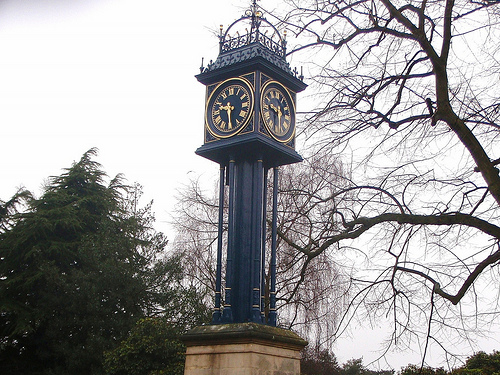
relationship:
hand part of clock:
[275, 110, 285, 132] [197, 74, 263, 142]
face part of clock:
[208, 82, 252, 130] [197, 74, 263, 142]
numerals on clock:
[240, 107, 247, 115] [203, 77, 254, 140]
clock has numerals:
[203, 77, 254, 140] [240, 107, 247, 115]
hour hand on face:
[217, 103, 235, 110] [211, 84, 249, 128]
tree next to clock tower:
[2, 145, 214, 374] [183, 0, 308, 374]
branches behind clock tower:
[176, 163, 498, 338] [180, 0, 309, 374]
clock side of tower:
[197, 74, 263, 142] [189, 0, 318, 342]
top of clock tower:
[188, 4, 300, 76] [192, 1, 310, 316]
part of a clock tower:
[109, 320, 403, 372] [180, 0, 309, 374]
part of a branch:
[212, 231, 460, 339] [292, 174, 498, 298]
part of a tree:
[433, 204, 493, 293] [86, 197, 161, 268]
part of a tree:
[474, 233, 489, 265] [246, 2, 498, 367]